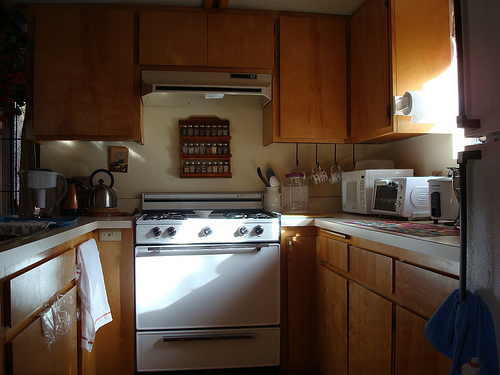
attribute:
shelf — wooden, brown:
[177, 116, 232, 179]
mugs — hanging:
[291, 163, 356, 185]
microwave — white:
[340, 169, 414, 216]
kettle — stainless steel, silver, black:
[78, 169, 118, 209]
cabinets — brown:
[0, 226, 462, 373]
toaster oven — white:
[370, 175, 445, 221]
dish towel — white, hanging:
[75, 238, 114, 353]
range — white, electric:
[139, 70, 273, 111]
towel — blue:
[425, 287, 497, 374]